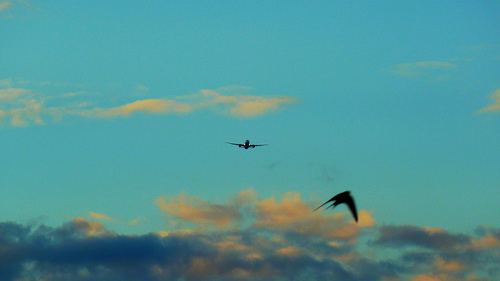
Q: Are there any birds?
A: Yes, there is a bird.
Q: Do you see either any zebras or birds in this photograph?
A: Yes, there is a bird.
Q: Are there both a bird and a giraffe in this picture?
A: No, there is a bird but no giraffes.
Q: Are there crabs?
A: No, there are no crabs.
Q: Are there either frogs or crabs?
A: No, there are no crabs or frogs.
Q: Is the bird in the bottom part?
A: Yes, the bird is in the bottom of the image.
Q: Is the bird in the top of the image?
A: No, the bird is in the bottom of the image.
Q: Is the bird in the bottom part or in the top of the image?
A: The bird is in the bottom of the image.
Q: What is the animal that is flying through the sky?
A: The animal is a bird.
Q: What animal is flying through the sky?
A: The animal is a bird.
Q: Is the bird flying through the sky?
A: Yes, the bird is flying through the sky.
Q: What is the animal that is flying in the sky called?
A: The animal is a bird.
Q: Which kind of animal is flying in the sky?
A: The animal is a bird.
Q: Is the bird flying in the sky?
A: Yes, the bird is flying in the sky.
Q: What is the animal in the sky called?
A: The animal is a bird.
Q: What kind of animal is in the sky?
A: The animal is a bird.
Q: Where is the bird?
A: The bird is in the sky.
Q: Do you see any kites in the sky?
A: No, there is a bird in the sky.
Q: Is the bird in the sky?
A: Yes, the bird is in the sky.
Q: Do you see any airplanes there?
A: Yes, there is an airplane.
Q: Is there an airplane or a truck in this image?
A: Yes, there is an airplane.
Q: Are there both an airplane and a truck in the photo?
A: No, there is an airplane but no trucks.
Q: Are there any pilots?
A: No, there are no pilots.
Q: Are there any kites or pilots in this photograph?
A: No, there are no pilots or kites.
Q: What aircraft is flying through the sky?
A: The aircraft is an airplane.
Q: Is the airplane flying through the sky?
A: Yes, the airplane is flying through the sky.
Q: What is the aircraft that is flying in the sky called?
A: The aircraft is an airplane.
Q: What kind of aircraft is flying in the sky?
A: The aircraft is an airplane.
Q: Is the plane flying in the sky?
A: Yes, the plane is flying in the sky.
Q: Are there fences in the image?
A: No, there are no fences.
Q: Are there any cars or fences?
A: No, there are no fences or cars.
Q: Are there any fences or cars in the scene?
A: No, there are no fences or cars.